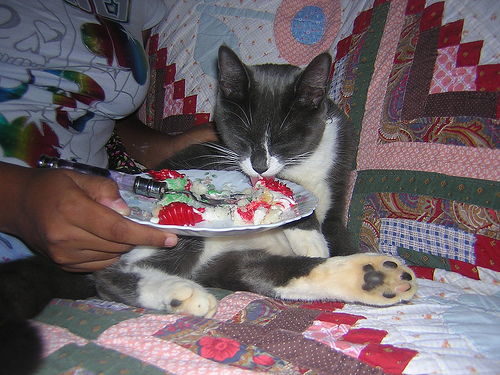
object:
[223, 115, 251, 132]
eye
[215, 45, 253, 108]
ear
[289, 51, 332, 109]
ear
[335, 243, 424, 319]
cat's paw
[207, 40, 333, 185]
head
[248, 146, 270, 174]
nose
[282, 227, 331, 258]
mitten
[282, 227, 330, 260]
front paw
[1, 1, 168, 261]
shirt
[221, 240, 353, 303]
leg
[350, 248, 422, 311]
paw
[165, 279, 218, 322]
paw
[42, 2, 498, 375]
quilt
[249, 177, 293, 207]
icing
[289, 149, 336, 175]
whisker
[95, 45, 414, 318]
cat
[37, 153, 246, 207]
fork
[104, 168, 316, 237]
plate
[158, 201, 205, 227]
red frosting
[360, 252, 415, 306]
pads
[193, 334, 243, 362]
rose shapes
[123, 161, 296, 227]
cake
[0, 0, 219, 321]
woman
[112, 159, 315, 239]
white plate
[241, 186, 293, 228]
pink flowers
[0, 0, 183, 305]
woman holding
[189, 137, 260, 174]
whiskers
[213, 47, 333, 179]
face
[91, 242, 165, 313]
leg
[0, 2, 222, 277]
person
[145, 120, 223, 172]
hand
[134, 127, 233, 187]
back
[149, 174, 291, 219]
cake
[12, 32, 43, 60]
heart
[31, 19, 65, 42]
heart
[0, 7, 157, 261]
woman's shirt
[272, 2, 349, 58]
circular shapes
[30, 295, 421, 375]
bedspread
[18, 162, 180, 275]
hand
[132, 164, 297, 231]
food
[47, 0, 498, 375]
couch